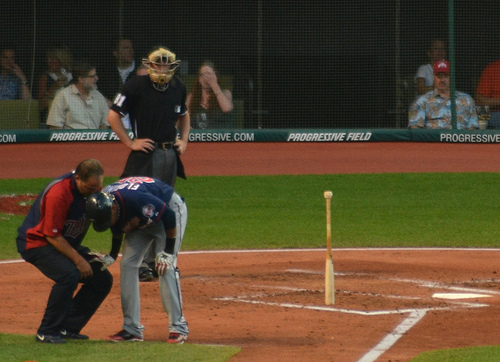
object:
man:
[16, 158, 114, 344]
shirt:
[16, 171, 103, 252]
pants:
[21, 245, 114, 337]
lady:
[176, 62, 234, 129]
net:
[0, 0, 500, 129]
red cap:
[433, 60, 449, 75]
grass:
[214, 189, 316, 233]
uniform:
[16, 174, 114, 335]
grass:
[0, 332, 242, 362]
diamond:
[235, 288, 491, 315]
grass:
[0, 242, 9, 260]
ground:
[313, 151, 345, 164]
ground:
[435, 146, 464, 166]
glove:
[154, 251, 174, 276]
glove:
[88, 252, 116, 272]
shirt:
[95, 176, 176, 234]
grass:
[0, 180, 35, 189]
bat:
[323, 191, 335, 306]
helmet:
[142, 47, 181, 91]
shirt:
[408, 88, 480, 129]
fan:
[407, 61, 480, 130]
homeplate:
[432, 293, 492, 300]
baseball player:
[85, 176, 189, 344]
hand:
[201, 68, 217, 83]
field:
[0, 142, 500, 362]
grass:
[436, 198, 494, 246]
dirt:
[175, 252, 492, 352]